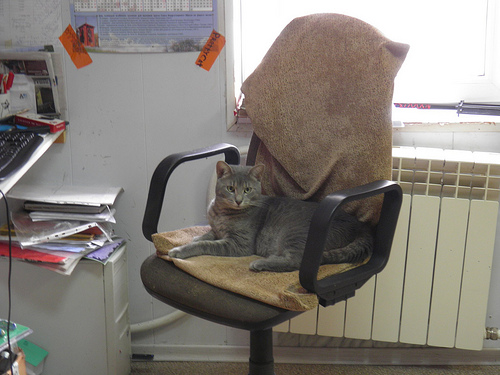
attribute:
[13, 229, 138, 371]
unit — tall, white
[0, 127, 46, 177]
keyboard — black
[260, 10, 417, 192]
towel — brown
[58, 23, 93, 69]
tape — orange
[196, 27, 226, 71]
tape — orange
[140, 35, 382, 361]
chair — gray, black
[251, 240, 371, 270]
tail — black and white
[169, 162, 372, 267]
cat — grey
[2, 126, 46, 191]
keyboard — black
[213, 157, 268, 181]
ears — grey, pointy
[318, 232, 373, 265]
tail — cat's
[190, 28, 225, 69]
tape — Orange 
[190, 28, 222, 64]
writing — black 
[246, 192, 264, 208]
whiskes — white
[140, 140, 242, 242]
arm rest — black